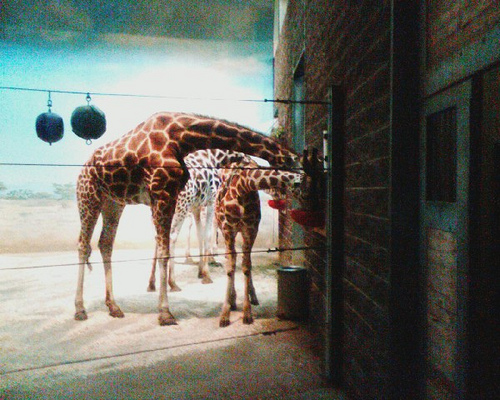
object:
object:
[69, 102, 106, 140]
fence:
[0, 88, 338, 385]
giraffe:
[74, 108, 320, 331]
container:
[276, 267, 311, 322]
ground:
[6, 251, 328, 399]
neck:
[173, 113, 304, 179]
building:
[270, 0, 500, 399]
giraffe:
[212, 148, 320, 327]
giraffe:
[157, 145, 227, 270]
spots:
[122, 152, 140, 170]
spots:
[221, 179, 259, 233]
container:
[36, 112, 64, 143]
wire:
[0, 161, 338, 171]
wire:
[1, 244, 330, 274]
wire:
[2, 319, 325, 378]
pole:
[325, 85, 345, 382]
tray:
[291, 207, 329, 228]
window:
[422, 108, 459, 204]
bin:
[268, 194, 288, 214]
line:
[0, 84, 335, 106]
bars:
[428, 110, 460, 201]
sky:
[1, 0, 282, 201]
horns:
[299, 150, 312, 164]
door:
[283, 61, 308, 263]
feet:
[76, 304, 84, 317]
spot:
[147, 151, 166, 171]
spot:
[227, 205, 243, 218]